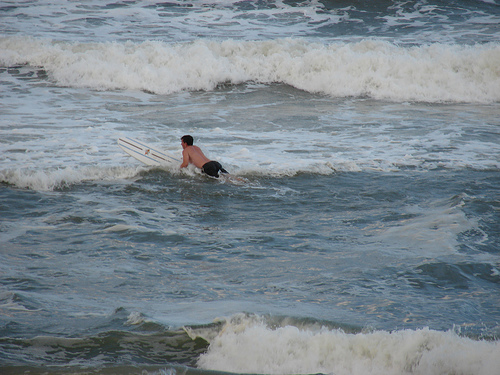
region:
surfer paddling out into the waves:
[103, 115, 238, 207]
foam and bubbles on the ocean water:
[126, 307, 418, 370]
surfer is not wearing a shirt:
[170, 120, 234, 193]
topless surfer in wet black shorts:
[191, 160, 280, 192]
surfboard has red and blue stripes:
[92, 126, 169, 179]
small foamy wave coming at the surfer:
[22, 20, 462, 122]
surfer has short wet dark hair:
[174, 130, 210, 152]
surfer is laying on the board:
[162, 130, 227, 198]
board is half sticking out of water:
[118, 121, 183, 174]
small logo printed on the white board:
[137, 144, 157, 160]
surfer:
[154, 115, 226, 210]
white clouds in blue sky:
[438, 3, 469, 45]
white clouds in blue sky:
[277, 22, 314, 46]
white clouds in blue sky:
[90, 25, 167, 62]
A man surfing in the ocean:
[111, 116, 247, 191]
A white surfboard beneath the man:
[114, 131, 191, 176]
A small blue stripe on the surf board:
[121, 144, 164, 164]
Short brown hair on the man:
[179, 131, 193, 147]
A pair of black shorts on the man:
[198, 159, 236, 181]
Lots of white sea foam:
[63, 32, 455, 102]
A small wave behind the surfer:
[10, 24, 490, 116]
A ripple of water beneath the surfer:
[27, 160, 302, 203]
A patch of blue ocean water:
[296, 170, 396, 211]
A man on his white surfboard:
[112, 129, 249, 190]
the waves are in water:
[14, 130, 161, 322]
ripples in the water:
[287, 170, 466, 313]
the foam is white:
[230, 53, 475, 128]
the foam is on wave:
[26, 57, 278, 109]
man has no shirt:
[182, 141, 210, 168]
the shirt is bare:
[184, 145, 209, 170]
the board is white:
[115, 130, 181, 181]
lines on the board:
[125, 139, 173, 166]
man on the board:
[126, 129, 233, 194]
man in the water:
[155, 117, 262, 207]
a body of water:
[68, 208, 129, 268]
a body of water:
[155, 205, 202, 262]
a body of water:
[249, 221, 304, 275]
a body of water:
[331, 208, 395, 260]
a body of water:
[405, 191, 470, 250]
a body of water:
[397, 275, 445, 329]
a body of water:
[287, 250, 345, 327]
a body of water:
[215, 256, 264, 321]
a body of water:
[127, 254, 187, 321]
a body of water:
[33, 258, 114, 318]